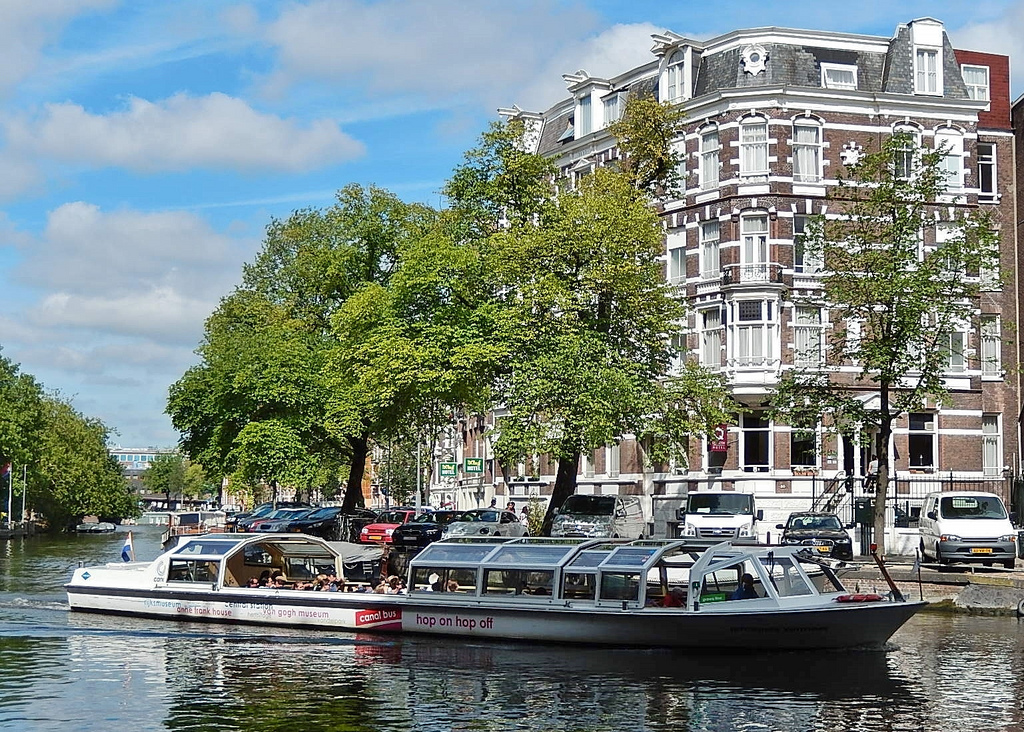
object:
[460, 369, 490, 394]
leaves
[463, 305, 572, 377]
leaves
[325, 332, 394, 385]
leaves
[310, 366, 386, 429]
leaves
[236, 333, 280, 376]
leaves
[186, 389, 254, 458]
leaves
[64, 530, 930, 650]
boat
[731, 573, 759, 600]
people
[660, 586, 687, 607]
people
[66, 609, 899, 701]
reflection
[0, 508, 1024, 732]
water